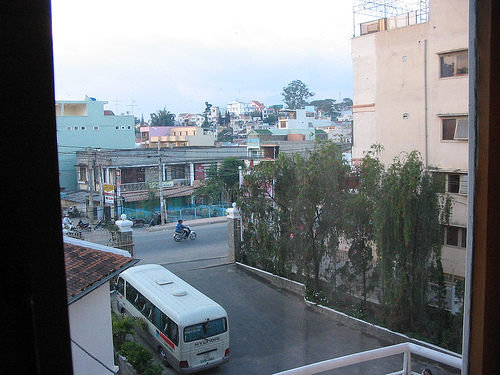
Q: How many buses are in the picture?
A: One.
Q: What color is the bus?
A: White.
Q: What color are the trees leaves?
A: Green.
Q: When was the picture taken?
A: During the day.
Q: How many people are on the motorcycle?
A: Two.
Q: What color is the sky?
A: Blue.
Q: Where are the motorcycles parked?
A: Across the street.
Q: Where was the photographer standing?
A: In front of window.